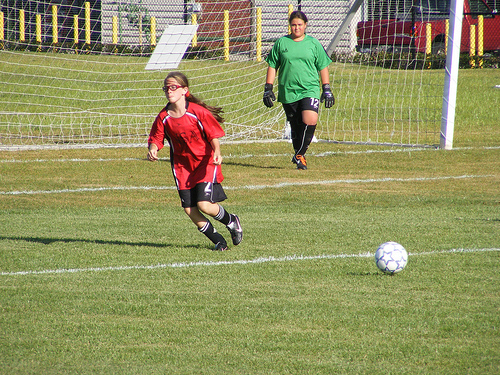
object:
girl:
[147, 71, 242, 251]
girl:
[262, 10, 335, 170]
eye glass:
[162, 85, 182, 92]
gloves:
[263, 83, 277, 108]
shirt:
[148, 102, 226, 190]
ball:
[375, 241, 409, 275]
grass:
[0, 59, 500, 131]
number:
[310, 97, 319, 109]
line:
[0, 246, 499, 276]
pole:
[223, 10, 230, 61]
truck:
[355, 0, 499, 58]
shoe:
[291, 154, 307, 170]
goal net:
[0, 0, 433, 151]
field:
[0, 133, 500, 375]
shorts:
[177, 182, 227, 208]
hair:
[164, 71, 226, 123]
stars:
[379, 251, 395, 265]